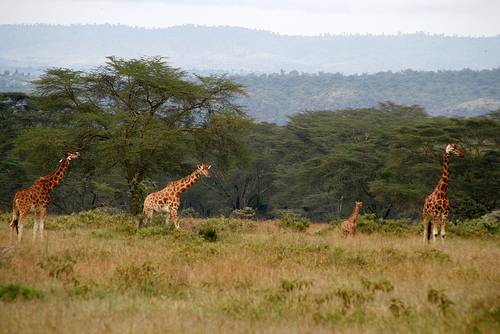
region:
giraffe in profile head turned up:
[8, 142, 86, 245]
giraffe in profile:
[138, 156, 219, 233]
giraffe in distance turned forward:
[330, 194, 370, 240]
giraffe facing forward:
[417, 139, 468, 246]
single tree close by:
[25, 52, 258, 208]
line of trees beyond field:
[2, 94, 497, 245]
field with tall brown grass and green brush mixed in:
[5, 248, 493, 313]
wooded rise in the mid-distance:
[249, 68, 498, 128]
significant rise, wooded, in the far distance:
[1, 19, 498, 79]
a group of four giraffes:
[8, 120, 478, 256]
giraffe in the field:
[147, 178, 204, 228]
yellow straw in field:
[231, 248, 400, 316]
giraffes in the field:
[15, 139, 455, 254]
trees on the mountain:
[242, 78, 412, 110]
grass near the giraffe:
[64, 193, 166, 246]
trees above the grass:
[55, 52, 231, 132]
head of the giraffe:
[190, 160, 212, 185]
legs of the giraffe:
[409, 217, 450, 244]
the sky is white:
[275, 15, 446, 39]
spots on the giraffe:
[144, 192, 178, 206]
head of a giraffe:
[56, 146, 83, 162]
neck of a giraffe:
[46, 159, 67, 185]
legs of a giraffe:
[6, 208, 56, 256]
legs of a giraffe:
[138, 210, 192, 238]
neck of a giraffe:
[172, 165, 200, 196]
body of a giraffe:
[136, 183, 183, 217]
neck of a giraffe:
[434, 156, 451, 191]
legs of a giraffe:
[418, 209, 455, 246]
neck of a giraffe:
[349, 205, 365, 219]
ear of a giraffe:
[446, 135, 456, 151]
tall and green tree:
[44, 57, 226, 207]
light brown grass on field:
[74, 213, 391, 310]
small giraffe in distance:
[317, 197, 374, 239]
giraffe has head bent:
[108, 158, 216, 229]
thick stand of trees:
[272, 114, 427, 191]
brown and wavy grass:
[90, 240, 402, 312]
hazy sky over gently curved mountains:
[1, 2, 496, 68]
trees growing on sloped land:
[5, 66, 495, 126]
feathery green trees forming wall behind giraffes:
[0, 55, 490, 241]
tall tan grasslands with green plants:
[2, 212, 492, 327]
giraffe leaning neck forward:
[140, 156, 210, 226]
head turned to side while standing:
[415, 135, 462, 240]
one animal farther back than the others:
[6, 135, 463, 240]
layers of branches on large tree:
[28, 50, 250, 220]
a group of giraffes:
[0, 118, 494, 274]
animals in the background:
[12, 56, 474, 261]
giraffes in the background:
[13, 57, 482, 329]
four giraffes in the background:
[9, 50, 496, 307]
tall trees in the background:
[12, 27, 491, 283]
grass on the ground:
[69, 227, 499, 317]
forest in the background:
[13, 35, 495, 307]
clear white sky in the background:
[70, 13, 495, 84]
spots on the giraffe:
[138, 118, 242, 260]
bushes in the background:
[52, 198, 498, 253]